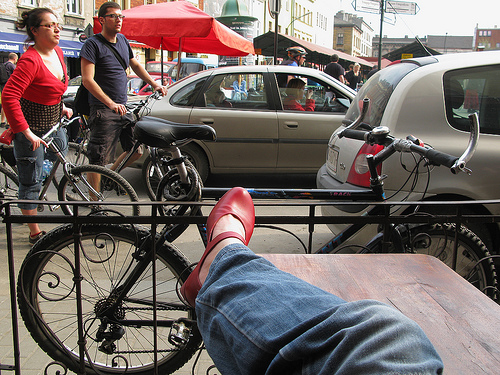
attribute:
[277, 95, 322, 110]
shirt — red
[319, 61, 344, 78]
shirt — black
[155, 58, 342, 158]
tan sedan — small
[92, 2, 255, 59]
umbrella — large, red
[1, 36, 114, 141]
shirt —  red,  girl's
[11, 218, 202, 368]
tire — bicycle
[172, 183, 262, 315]
shoe — red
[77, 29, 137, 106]
shirt — blue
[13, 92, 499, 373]
bicycle — black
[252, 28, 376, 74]
black canopy — large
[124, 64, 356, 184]
car — beige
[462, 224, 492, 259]
tread — thick